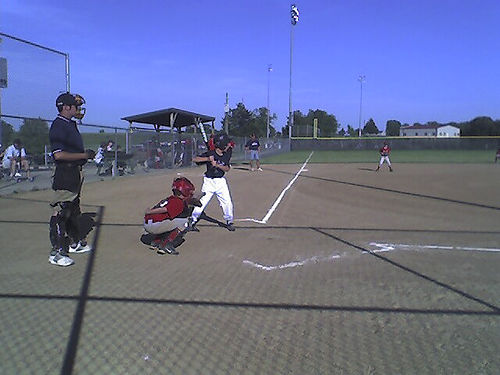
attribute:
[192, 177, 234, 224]
pants — white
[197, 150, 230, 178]
shirt — black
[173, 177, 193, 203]
helmet — red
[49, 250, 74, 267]
shoe — white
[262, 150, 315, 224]
line — white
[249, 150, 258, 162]
shorts — blue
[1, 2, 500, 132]
sky — cloudless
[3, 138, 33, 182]
man — sitting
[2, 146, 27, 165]
shirt — white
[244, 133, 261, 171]
person — standing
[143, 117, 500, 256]
people — playing